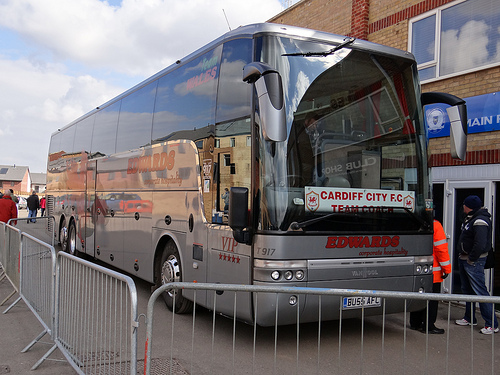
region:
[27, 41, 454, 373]
a bus on the road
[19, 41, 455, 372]
a bus on the street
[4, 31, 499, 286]
a passenger bus on the road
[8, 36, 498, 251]
a passenger bus on the street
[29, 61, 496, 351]
a bus gated in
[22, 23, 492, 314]
a bus that is fenced in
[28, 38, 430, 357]
a bus that is silver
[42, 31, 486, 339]
a large bus that is silver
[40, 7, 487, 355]
a large silver bus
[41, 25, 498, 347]
a large passenger bus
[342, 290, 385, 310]
A license plate on the front of a bus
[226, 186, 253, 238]
A bus's side mirror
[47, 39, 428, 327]
A large silver bus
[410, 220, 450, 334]
A man wearing an orange safety jacket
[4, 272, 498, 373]
A silver metal barrier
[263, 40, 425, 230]
The front window of a bus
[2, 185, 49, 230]
A group of people standing behind the bus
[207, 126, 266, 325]
The closed bus door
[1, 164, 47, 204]
A few houses across the street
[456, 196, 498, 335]
A man standing in front of a building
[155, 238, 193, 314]
a bus front right tire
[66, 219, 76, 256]
a bus rear left tire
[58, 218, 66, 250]
a bus rear left tire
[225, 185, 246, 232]
a black rear view mirror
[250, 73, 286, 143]
a large silver and black rear view mirror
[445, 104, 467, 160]
a large silver and black rear view mirror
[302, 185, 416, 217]
a bus destination sign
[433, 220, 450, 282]
an orange and white safety jacket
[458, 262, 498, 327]
a pair of blue jeans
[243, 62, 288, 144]
the side view mirror of the bus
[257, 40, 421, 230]
the windshield of the bus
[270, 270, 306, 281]
the headlights of the bus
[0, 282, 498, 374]
metal safety rail and barricade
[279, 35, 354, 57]
the buses windshield wiper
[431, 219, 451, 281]
a man in an orange safety jacket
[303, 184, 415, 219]
the business banner advertisement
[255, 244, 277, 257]
the bus identification number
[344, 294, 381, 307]
the bus license plate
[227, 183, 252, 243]
the secondary side view mirror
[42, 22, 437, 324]
Silver travel bus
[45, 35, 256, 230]
Dark shaded windows of a bus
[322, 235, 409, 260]
Red company letters on the front of a bus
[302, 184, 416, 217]
White and red sign in the bus window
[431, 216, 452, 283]
Orange coat with silver reflector strips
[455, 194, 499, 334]
Man standing with his hand in his pocket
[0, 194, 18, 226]
Red poof winter coat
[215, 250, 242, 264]
Five red stars in a row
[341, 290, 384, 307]
White license plate with black letters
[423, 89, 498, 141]
Blue sign on a building